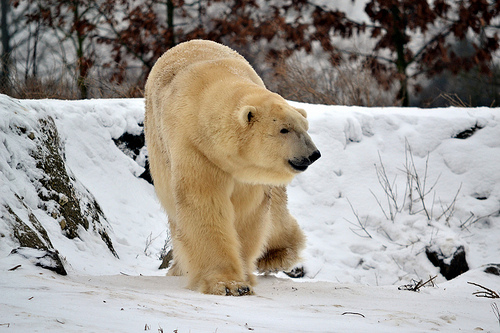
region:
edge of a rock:
[65, 180, 107, 231]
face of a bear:
[303, 138, 323, 165]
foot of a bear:
[230, 258, 238, 272]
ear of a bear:
[236, 103, 259, 117]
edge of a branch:
[397, 55, 403, 79]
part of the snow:
[411, 213, 419, 258]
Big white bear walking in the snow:
[140, 36, 332, 296]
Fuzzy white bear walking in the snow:
[137, 38, 325, 300]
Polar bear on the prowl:
[140, 35, 326, 297]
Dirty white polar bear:
[140, 35, 322, 300]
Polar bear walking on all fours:
[141, 36, 326, 303]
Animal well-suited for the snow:
[141, 36, 323, 299]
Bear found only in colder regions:
[143, 33, 321, 306]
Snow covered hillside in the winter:
[1, 94, 498, 331]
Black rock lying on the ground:
[426, 236, 473, 283]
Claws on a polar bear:
[224, 284, 252, 294]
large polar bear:
[129, 19, 336, 297]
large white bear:
[123, 45, 349, 292]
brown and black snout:
[273, 135, 322, 173]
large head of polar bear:
[218, 97, 328, 184]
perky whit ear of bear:
[232, 98, 262, 130]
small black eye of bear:
[279, 126, 291, 133]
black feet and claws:
[217, 280, 258, 298]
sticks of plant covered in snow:
[335, 142, 476, 279]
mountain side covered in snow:
[0, 75, 87, 255]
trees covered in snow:
[272, 6, 467, 100]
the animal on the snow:
[142, 37, 318, 299]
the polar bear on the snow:
[140, 30, 321, 295]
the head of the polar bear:
[235, 91, 322, 183]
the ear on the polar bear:
[238, 103, 254, 128]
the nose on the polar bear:
[306, 146, 319, 161]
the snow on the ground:
[10, 95, 496, 325]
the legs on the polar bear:
[141, 170, 316, 297]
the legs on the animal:
[145, 181, 305, 296]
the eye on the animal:
[276, 122, 286, 132]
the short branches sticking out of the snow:
[346, 135, 473, 239]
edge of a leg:
[215, 264, 256, 299]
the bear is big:
[149, 48, 330, 294]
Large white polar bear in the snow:
[125, 29, 360, 320]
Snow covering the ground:
[15, 237, 62, 304]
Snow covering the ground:
[3, 81, 61, 149]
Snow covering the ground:
[10, 156, 82, 233]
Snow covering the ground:
[390, 234, 462, 306]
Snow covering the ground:
[268, 293, 320, 327]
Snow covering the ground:
[406, 86, 493, 167]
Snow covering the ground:
[285, 84, 417, 169]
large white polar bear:
[141, 38, 321, 298]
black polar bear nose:
[305, 145, 323, 162]